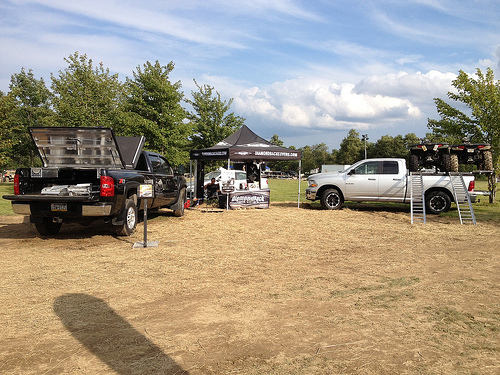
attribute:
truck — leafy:
[13, 113, 194, 243]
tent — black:
[189, 123, 297, 209]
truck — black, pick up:
[6, 120, 190, 242]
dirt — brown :
[6, 218, 497, 373]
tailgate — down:
[2, 186, 103, 211]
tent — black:
[182, 107, 331, 220]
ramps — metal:
[400, 169, 439, 244]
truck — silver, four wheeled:
[303, 157, 492, 214]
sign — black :
[130, 176, 158, 253]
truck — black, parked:
[18, 114, 188, 249]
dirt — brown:
[0, 197, 497, 374]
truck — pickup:
[321, 140, 461, 242]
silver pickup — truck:
[299, 156, 481, 213]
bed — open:
[11, 167, 110, 203]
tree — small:
[113, 62, 195, 187]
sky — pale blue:
[13, 6, 498, 75]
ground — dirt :
[0, 176, 496, 373]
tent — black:
[188, 126, 302, 160]